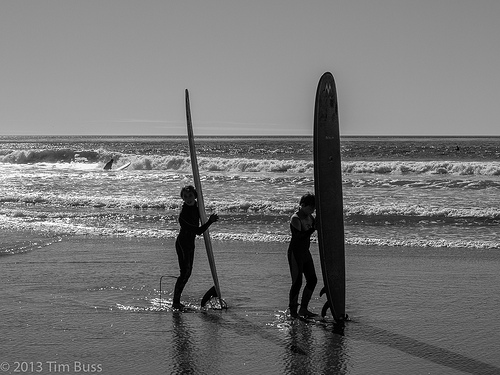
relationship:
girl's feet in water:
[286, 307, 318, 321] [1, 237, 164, 374]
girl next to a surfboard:
[286, 193, 320, 319] [314, 70, 347, 324]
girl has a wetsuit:
[172, 185, 199, 310] [172, 202, 201, 311]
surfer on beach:
[286, 193, 320, 319] [0, 227, 172, 373]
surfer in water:
[172, 185, 199, 310] [1, 237, 164, 374]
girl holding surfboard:
[173, 187, 218, 308] [185, 87, 226, 311]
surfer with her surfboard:
[286, 193, 320, 319] [314, 70, 347, 324]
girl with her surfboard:
[286, 193, 320, 319] [314, 70, 347, 324]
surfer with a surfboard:
[172, 185, 199, 310] [185, 87, 226, 311]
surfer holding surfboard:
[173, 187, 218, 308] [185, 87, 226, 311]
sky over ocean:
[1, 1, 500, 73] [1, 136, 175, 241]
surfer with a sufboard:
[173, 187, 218, 308] [185, 87, 226, 311]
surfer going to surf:
[286, 193, 320, 319] [286, 71, 346, 328]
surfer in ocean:
[103, 158, 131, 175] [1, 136, 175, 241]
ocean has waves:
[347, 140, 499, 252] [2, 143, 184, 175]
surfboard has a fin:
[185, 87, 226, 311] [199, 285, 216, 316]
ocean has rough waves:
[1, 136, 175, 241] [2, 143, 184, 175]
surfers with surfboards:
[286, 193, 320, 319] [314, 70, 347, 324]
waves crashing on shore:
[2, 143, 184, 175] [345, 183, 500, 275]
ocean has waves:
[1, 136, 175, 241] [2, 143, 184, 175]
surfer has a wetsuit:
[172, 185, 199, 310] [172, 202, 201, 311]